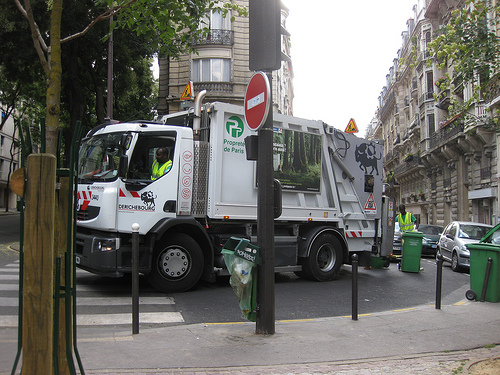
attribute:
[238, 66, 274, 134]
sign — red, white, silver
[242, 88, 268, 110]
dash — white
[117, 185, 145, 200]
stripe — red, white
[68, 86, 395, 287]
truck — property of paris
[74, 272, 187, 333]
stripes — white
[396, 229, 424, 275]
garbage — tall, green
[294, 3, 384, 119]
sky — grey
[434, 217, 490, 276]
car — silver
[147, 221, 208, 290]
wheel — large, black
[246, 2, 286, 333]
pole — grey, black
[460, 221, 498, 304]
garbage can — green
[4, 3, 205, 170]
tree — leafy green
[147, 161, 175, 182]
vest — green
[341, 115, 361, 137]
sign — yellow, black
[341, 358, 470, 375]
sidewalk — bricks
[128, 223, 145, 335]
pole — small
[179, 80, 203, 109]
sign — orange, yellow